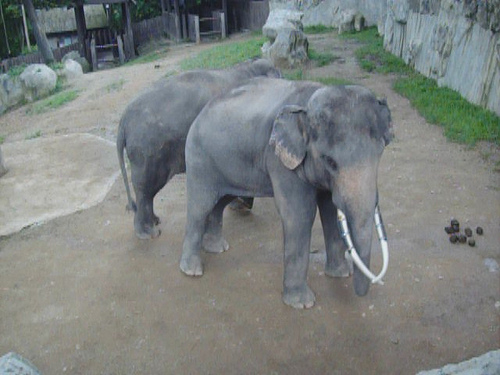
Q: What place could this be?
A: It is a pen.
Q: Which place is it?
A: It is a pen.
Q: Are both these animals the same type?
A: Yes, all the animals are elephants.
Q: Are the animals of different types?
A: No, all the animals are elephants.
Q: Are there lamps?
A: No, there are no lamps.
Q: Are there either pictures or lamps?
A: No, there are no lamps or pictures.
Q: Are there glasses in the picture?
A: No, there are no glasses.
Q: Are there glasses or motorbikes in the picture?
A: No, there are no glasses or motorbikes.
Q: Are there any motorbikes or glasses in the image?
A: No, there are no glasses or motorbikes.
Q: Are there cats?
A: No, there are no cats.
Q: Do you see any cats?
A: No, there are no cats.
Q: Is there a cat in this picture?
A: No, there are no cats.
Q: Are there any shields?
A: No, there are no shields.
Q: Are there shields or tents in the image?
A: No, there are no shields or tents.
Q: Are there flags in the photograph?
A: No, there are no flags.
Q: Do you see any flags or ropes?
A: No, there are no flags or ropes.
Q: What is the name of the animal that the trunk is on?
A: The animal is an elephant.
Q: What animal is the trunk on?
A: The trunk is on the elephant.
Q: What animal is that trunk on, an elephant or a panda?
A: The trunk is on an elephant.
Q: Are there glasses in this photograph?
A: No, there are no glasses.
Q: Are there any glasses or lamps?
A: No, there are no glasses or lamps.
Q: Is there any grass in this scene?
A: Yes, there is grass.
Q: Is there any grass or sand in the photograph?
A: Yes, there is grass.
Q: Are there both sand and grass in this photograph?
A: No, there is grass but no sand.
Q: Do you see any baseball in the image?
A: No, there are no baseballs.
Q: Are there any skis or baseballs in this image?
A: No, there are no baseballs or skis.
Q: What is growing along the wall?
A: The grass is growing along the wall.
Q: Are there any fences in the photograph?
A: Yes, there is a fence.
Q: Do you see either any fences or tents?
A: Yes, there is a fence.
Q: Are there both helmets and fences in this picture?
A: No, there is a fence but no helmets.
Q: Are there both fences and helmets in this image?
A: No, there is a fence but no helmets.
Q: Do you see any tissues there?
A: No, there are no tissues.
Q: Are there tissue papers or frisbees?
A: No, there are no tissue papers or frisbees.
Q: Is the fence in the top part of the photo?
A: Yes, the fence is in the top of the image.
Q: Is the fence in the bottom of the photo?
A: No, the fence is in the top of the image.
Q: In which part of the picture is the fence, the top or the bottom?
A: The fence is in the top of the image.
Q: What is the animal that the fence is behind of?
A: The animal is an elephant.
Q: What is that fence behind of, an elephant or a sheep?
A: The fence is behind an elephant.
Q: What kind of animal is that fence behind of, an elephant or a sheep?
A: The fence is behind an elephant.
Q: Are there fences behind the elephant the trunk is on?
A: Yes, there is a fence behind the elephant.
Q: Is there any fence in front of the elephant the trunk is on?
A: No, the fence is behind the elephant.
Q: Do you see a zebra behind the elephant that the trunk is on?
A: No, there is a fence behind the elephant.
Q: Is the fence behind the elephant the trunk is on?
A: Yes, the fence is behind the elephant.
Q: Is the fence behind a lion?
A: No, the fence is behind the elephant.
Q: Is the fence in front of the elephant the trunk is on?
A: No, the fence is behind the elephant.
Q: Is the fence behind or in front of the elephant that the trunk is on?
A: The fence is behind the elephant.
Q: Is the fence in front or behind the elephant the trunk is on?
A: The fence is behind the elephant.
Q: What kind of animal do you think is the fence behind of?
A: The fence is behind the elephant.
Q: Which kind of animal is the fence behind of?
A: The fence is behind the elephant.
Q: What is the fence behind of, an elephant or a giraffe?
A: The fence is behind an elephant.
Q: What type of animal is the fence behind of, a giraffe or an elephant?
A: The fence is behind an elephant.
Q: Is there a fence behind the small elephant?
A: Yes, there is a fence behind the elephant.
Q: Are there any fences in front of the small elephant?
A: No, the fence is behind the elephant.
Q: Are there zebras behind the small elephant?
A: No, there is a fence behind the elephant.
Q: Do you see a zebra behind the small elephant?
A: No, there is a fence behind the elephant.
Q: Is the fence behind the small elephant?
A: Yes, the fence is behind the elephant.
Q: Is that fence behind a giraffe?
A: No, the fence is behind the elephant.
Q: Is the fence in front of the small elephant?
A: No, the fence is behind the elephant.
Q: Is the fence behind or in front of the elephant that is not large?
A: The fence is behind the elephant.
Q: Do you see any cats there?
A: No, there are no cats.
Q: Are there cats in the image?
A: No, there are no cats.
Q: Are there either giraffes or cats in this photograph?
A: No, there are no cats or giraffes.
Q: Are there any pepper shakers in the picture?
A: No, there are no pepper shakers.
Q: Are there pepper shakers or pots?
A: No, there are no pepper shakers or pots.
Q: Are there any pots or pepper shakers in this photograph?
A: No, there are no pepper shakers or pots.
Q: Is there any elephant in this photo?
A: Yes, there is an elephant.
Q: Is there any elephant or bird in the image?
A: Yes, there is an elephant.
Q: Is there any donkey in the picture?
A: No, there are no donkeys.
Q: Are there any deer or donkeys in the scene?
A: No, there are no donkeys or deer.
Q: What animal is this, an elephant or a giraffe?
A: This is an elephant.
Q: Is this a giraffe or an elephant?
A: This is an elephant.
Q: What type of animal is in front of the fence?
A: The animal is an elephant.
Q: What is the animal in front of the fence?
A: The animal is an elephant.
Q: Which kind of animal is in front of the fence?
A: The animal is an elephant.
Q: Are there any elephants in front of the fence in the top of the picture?
A: Yes, there is an elephant in front of the fence.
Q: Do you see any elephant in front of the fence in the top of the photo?
A: Yes, there is an elephant in front of the fence.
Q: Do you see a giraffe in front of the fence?
A: No, there is an elephant in front of the fence.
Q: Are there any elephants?
A: Yes, there is an elephant.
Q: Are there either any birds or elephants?
A: Yes, there is an elephant.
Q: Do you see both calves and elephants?
A: No, there is an elephant but no calves.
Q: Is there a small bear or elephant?
A: Yes, there is a small elephant.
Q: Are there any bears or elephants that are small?
A: Yes, the elephant is small.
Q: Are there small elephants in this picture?
A: Yes, there is a small elephant.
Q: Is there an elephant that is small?
A: Yes, there is an elephant that is small.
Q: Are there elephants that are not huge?
A: Yes, there is a small elephant.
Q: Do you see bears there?
A: No, there are no bears.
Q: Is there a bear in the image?
A: No, there are no bears.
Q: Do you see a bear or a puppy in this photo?
A: No, there are no bears or puppys.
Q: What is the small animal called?
A: The animal is an elephant.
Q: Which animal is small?
A: The animal is an elephant.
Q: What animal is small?
A: The animal is an elephant.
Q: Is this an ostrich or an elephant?
A: This is an elephant.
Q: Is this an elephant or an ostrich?
A: This is an elephant.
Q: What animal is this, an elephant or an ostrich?
A: This is an elephant.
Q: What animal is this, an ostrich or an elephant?
A: This is an elephant.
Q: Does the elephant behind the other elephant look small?
A: Yes, the elephant is small.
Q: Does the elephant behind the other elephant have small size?
A: Yes, the elephant is small.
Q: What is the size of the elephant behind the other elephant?
A: The elephant is small.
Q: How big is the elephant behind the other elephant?
A: The elephant is small.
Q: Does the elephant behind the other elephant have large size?
A: No, the elephant is small.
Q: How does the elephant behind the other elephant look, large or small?
A: The elephant is small.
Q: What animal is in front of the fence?
A: The elephant is in front of the fence.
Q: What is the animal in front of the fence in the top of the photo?
A: The animal is an elephant.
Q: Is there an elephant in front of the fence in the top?
A: Yes, there is an elephant in front of the fence.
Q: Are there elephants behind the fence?
A: No, the elephant is in front of the fence.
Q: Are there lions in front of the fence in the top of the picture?
A: No, there is an elephant in front of the fence.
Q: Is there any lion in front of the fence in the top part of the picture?
A: No, there is an elephant in front of the fence.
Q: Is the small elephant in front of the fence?
A: Yes, the elephant is in front of the fence.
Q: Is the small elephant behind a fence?
A: No, the elephant is in front of a fence.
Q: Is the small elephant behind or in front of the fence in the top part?
A: The elephant is in front of the fence.